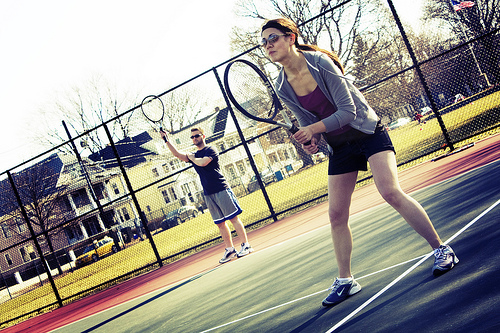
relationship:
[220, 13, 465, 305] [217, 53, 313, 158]
woman holding racket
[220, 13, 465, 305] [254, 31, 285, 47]
woman wearing sunglasess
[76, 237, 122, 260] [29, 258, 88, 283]
car on street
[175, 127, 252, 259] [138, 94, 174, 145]
man holding racket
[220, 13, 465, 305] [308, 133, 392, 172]
woman wearing shorts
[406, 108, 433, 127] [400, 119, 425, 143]
child running on grass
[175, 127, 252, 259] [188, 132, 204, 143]
man with sunglasses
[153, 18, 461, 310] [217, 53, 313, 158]
two persons holding racket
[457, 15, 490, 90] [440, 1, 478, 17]
post holding flag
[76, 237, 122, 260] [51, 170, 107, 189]
car on distance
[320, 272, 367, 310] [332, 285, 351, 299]
shoes with nike logo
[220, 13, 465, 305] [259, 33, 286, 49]
woman wearing sunglasses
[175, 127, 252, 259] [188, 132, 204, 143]
man wearing sunglasses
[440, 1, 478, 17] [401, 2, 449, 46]
flag in background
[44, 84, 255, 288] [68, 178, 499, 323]
fence surrounding tennis court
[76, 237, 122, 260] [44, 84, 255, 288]
cab parked beside fence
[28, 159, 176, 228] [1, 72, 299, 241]
row of house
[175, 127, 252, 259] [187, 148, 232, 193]
man wearing a tshirt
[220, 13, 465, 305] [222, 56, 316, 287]
woman playing tennis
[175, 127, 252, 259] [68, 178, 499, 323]
man standing on tennis court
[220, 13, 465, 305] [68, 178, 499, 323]
woman standing on tennis court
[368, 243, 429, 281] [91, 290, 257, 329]
white lines on ground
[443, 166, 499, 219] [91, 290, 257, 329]
shadow on ground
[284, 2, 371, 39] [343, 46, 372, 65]
tree with no leaves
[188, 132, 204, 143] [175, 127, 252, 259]
sunglasses on person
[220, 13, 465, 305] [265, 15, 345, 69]
person has long hair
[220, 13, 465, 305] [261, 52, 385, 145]
person wearing gray sweatshirt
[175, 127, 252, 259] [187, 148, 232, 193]
person wearing purple shirt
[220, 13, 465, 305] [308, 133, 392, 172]
person wearing black shorts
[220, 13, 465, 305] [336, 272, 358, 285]
person wearing white socks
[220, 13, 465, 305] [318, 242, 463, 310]
person wearing nike tennis shoes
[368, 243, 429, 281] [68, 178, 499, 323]
white lines on tennis court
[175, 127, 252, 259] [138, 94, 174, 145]
person holding ten racket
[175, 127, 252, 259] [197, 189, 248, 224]
person wearing grey shorts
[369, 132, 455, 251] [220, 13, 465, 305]
leg of a person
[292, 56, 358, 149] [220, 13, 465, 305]
arm of a person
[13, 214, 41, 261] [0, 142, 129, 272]
windows of a building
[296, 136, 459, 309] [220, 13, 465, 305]
legs of a person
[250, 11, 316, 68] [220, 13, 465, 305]
head of a person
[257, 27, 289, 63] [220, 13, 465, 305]
face of a person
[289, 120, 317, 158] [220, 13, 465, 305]
hands of a person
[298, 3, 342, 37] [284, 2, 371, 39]
branches of a tree